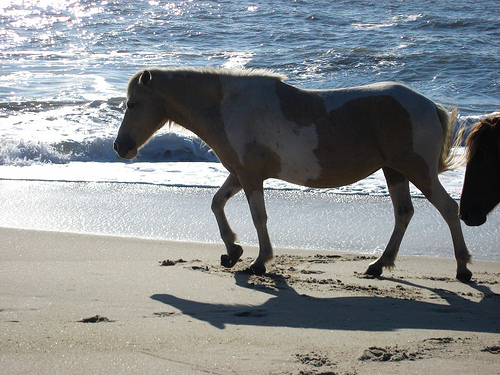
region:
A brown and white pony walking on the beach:
[103, 35, 484, 301]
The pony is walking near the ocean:
[86, 41, 451, 307]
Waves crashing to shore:
[26, 107, 113, 199]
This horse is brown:
[444, 110, 496, 254]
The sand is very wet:
[62, 269, 384, 370]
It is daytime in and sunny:
[1, 0, 109, 75]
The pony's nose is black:
[108, 123, 143, 170]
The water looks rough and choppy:
[120, 9, 446, 46]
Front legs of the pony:
[199, 167, 291, 282]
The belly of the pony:
[268, 97, 380, 189]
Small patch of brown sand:
[81, 237, 103, 275]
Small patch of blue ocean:
[211, 15, 244, 43]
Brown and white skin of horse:
[242, 100, 341, 168]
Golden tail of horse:
[443, 116, 452, 169]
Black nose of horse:
[111, 136, 131, 156]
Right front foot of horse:
[215, 232, 243, 267]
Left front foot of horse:
[252, 248, 274, 288]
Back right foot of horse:
[372, 243, 397, 280]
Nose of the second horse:
[456, 211, 476, 227]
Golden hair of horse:
[468, 125, 474, 158]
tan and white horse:
[111, 65, 473, 284]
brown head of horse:
[455, 110, 499, 226]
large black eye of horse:
[123, 98, 135, 110]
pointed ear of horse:
[138, 68, 154, 88]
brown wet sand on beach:
[1, 221, 497, 373]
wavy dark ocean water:
[1, 1, 499, 198]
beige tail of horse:
[433, 101, 469, 179]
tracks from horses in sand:
[158, 250, 498, 310]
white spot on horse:
[219, 73, 322, 191]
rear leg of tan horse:
[406, 168, 472, 283]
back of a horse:
[413, 140, 424, 155]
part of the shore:
[190, 328, 201, 338]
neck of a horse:
[194, 103, 199, 110]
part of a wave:
[80, 155, 97, 170]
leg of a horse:
[401, 200, 406, 224]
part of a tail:
[432, 125, 459, 208]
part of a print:
[292, 261, 302, 272]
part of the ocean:
[69, 155, 80, 175]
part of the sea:
[51, 110, 68, 133]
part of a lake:
[66, 157, 88, 196]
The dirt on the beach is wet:
[63, 294, 397, 371]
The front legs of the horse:
[206, 178, 278, 278]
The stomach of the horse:
[275, 84, 381, 191]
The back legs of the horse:
[363, 173, 474, 288]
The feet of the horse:
[218, 237, 267, 278]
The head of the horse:
[104, 63, 173, 162]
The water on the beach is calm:
[90, 20, 460, 64]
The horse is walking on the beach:
[109, 56, 478, 294]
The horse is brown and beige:
[101, 65, 460, 244]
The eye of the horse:
[111, 87, 148, 119]